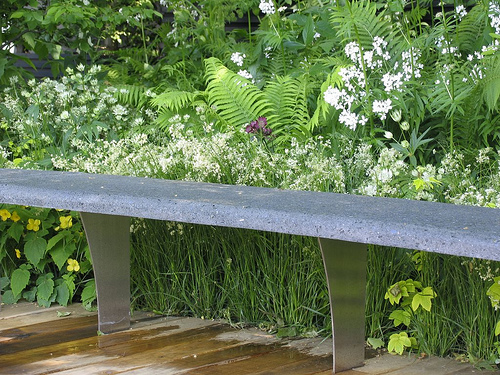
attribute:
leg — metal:
[80, 212, 133, 334]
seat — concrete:
[7, 169, 498, 252]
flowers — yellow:
[64, 256, 81, 272]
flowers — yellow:
[58, 212, 72, 229]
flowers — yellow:
[21, 216, 42, 232]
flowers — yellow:
[0, 209, 11, 224]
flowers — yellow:
[13, 246, 22, 258]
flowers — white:
[327, 40, 417, 121]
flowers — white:
[25, 216, 42, 233]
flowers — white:
[63, 259, 83, 275]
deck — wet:
[13, 280, 391, 371]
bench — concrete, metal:
[62, 154, 487, 302]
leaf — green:
[273, 72, 284, 79]